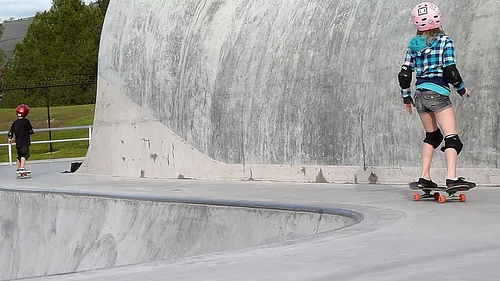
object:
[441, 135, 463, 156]
kneepad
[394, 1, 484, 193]
kids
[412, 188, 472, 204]
skateboards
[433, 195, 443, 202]
wheels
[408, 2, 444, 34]
helmet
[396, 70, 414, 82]
elbow pads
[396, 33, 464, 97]
shirt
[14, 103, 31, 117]
helmet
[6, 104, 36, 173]
boy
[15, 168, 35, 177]
skateboard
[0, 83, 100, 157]
fence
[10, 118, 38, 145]
shirt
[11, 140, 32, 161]
shorts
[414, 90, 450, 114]
shorts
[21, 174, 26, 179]
wheels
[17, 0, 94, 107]
tree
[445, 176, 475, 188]
shoes